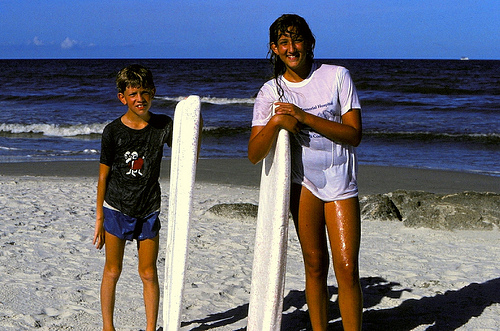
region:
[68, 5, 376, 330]
two people standing on the beach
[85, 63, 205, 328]
boy standing beside a surfboard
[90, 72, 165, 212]
boy wearing a black shirt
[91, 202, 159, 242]
boy wearing blue shorts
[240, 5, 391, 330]
woman leaning on a surfboard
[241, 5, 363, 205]
woman dressed in a white shirt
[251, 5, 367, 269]
woman's legs, shirt and hair appear to be wet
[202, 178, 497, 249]
rocks on the beach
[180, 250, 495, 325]
dark shadows on the sand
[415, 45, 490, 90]
distant object on the water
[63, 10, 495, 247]
two kids with boogie boards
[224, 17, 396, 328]
tan young girl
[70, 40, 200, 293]
tan young boy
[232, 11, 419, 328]
young girl with foam board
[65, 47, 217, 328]
young boy with foam board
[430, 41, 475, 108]
boat out on water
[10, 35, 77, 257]
water rolling in on beach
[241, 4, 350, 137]
girl with wet hair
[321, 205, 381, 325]
wet tan legs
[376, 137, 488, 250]
sand mounds on a beach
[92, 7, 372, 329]
two wet children on beach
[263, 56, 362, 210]
wet white tee shirt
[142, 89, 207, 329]
white Styrofoam surfboard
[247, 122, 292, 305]
white surfboard under arm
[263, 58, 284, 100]
wet hair on shoulder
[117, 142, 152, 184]
cartoon on tee shirt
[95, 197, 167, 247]
wet blue shorts on boy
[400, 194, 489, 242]
rocks in beach sand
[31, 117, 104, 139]
white cap of crashed wave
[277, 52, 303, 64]
smile on girl's face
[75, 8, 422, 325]
Two young people with their surfboards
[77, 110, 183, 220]
Young boy is wearing a black shirt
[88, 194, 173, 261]
Young boy is wearing blue swim trunks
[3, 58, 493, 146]
Water in the background is blue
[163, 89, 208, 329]
Surfboard is all white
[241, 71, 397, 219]
Young woman is wearing a white shirt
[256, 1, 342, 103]
Young girl's hair is wet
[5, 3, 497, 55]
The sky is clear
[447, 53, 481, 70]
A boat is in the background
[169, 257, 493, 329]
The people in this image shadows are on the sand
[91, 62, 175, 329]
boy wearing blue swim trunks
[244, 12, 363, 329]
girl wearing a white t-shirt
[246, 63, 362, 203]
t-shirt is wet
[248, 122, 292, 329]
girl leaning on white surfboard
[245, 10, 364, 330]
girl is standing on beach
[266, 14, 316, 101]
girl has wet brown hair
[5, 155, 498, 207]
sand next to the water is wet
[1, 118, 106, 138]
wave behind boy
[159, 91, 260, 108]
wave behind girl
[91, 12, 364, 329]
a girl standing to the right of a boy